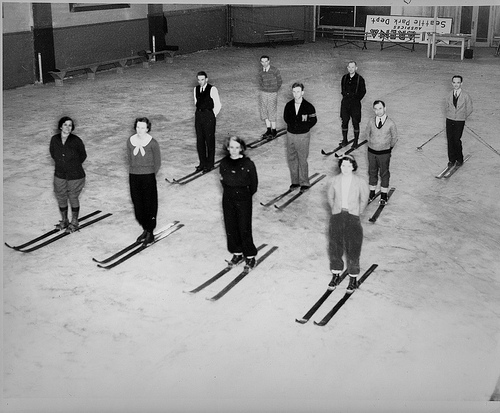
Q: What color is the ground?
A: Gray.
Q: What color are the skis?
A: Black.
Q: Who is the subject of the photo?
A: The skiers.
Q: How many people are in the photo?
A: 10.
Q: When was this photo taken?
A: During the day.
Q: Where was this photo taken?
A: At a ski lesson.